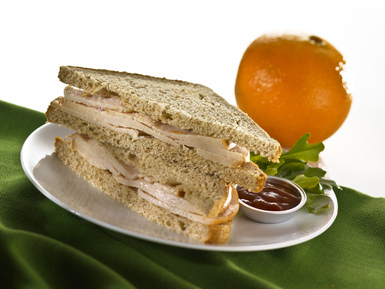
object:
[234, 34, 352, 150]
orange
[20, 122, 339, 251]
plate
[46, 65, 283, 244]
sandwhich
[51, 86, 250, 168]
meat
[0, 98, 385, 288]
table